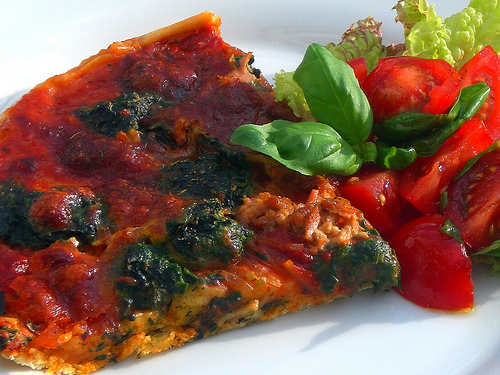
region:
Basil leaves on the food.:
[229, 43, 489, 181]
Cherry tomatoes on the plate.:
[345, 45, 497, 319]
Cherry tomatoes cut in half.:
[324, 24, 499, 316]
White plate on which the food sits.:
[1, 1, 492, 371]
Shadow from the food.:
[203, 259, 498, 373]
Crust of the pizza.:
[5, 6, 417, 371]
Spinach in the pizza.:
[3, 91, 403, 338]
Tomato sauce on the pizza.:
[3, 4, 398, 371]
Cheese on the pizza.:
[4, 162, 399, 361]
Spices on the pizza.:
[2, 9, 394, 372]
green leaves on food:
[244, 67, 418, 229]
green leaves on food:
[271, 24, 372, 178]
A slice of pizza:
[73, 36, 215, 307]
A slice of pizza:
[91, 90, 224, 247]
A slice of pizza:
[110, 108, 207, 210]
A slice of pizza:
[181, 120, 342, 367]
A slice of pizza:
[100, 102, 290, 336]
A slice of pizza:
[141, 187, 262, 349]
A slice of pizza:
[79, 216, 288, 359]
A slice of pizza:
[165, 159, 277, 276]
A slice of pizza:
[194, 199, 251, 272]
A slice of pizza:
[207, 237, 285, 332]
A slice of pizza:
[166, 237, 259, 339]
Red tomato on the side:
[391, 214, 483, 309]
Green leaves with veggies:
[294, 44, 401, 161]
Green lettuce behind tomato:
[381, 7, 499, 54]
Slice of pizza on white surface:
[16, 23, 368, 330]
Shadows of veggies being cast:
[280, 307, 410, 372]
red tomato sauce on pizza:
[10, 97, 79, 162]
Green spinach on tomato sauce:
[170, 203, 263, 263]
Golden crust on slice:
[87, 22, 164, 70]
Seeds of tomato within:
[463, 171, 473, 201]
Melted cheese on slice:
[138, 303, 233, 333]